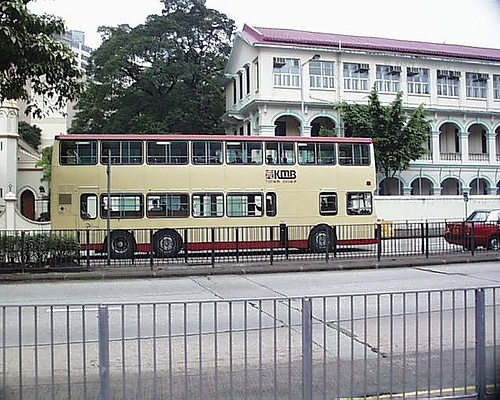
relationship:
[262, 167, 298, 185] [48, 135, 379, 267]
writing on side of bus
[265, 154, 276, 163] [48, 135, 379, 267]
person riding bus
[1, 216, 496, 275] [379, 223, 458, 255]
fence near road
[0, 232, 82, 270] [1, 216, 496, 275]
bushes near fence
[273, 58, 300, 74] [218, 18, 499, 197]
window on side of building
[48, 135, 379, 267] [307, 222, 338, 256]
bus has tire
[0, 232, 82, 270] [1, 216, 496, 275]
bushes along fence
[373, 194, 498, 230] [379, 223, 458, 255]
wall along road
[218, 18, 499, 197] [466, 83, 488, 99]
building has balcony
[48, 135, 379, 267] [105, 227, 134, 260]
bus has front wheel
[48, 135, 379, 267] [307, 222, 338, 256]
bus has back wheel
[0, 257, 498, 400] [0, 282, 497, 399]
pavement between railing